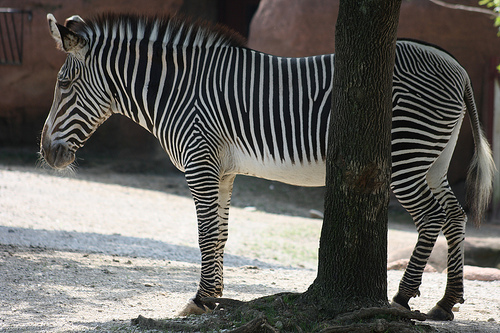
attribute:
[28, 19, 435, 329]
zebra — large, black, white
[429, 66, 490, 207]
tail — bushy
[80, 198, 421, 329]
ground — dirt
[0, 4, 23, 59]
attachment — metal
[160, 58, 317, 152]
stripes — black, white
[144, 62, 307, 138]
stripes — white, black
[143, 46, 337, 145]
stripes — black, white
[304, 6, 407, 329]
tree — brown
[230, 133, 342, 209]
belly — white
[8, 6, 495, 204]
wall — rocks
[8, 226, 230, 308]
shadow — tree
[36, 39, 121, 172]
face — sad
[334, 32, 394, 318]
tree — hardwood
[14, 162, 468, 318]
ground structure — sandy, loamy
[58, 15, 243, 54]
mane — zebra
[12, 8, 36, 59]
container — metal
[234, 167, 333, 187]
belly — zebra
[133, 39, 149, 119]
stripe — black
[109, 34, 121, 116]
stripe — black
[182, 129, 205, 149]
stripe — black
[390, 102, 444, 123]
stripe — black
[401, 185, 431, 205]
stripe — black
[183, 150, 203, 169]
strip — black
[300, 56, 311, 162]
strip — black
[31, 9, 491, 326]
zebra — black, white, striped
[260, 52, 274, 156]
stripe — black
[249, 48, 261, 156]
stripe — black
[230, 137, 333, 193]
belly — white